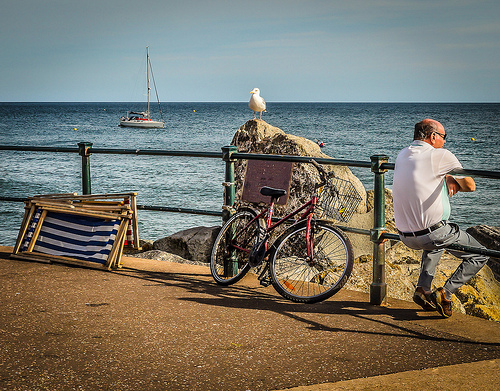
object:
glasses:
[431, 130, 447, 140]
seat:
[259, 186, 288, 198]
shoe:
[410, 289, 434, 313]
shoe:
[427, 287, 456, 317]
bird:
[248, 88, 268, 123]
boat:
[121, 43, 169, 131]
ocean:
[1, 103, 494, 281]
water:
[0, 102, 494, 245]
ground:
[0, 247, 498, 391]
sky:
[315, 12, 478, 96]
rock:
[122, 115, 498, 318]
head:
[414, 118, 446, 147]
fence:
[0, 140, 498, 315]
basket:
[319, 173, 363, 223]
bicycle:
[186, 158, 355, 304]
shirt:
[391, 139, 464, 233]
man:
[391, 114, 489, 319]